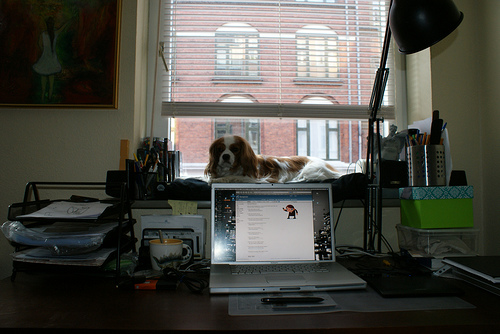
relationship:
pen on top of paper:
[258, 289, 330, 308] [282, 291, 339, 312]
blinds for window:
[155, 0, 398, 122] [154, 7, 415, 181]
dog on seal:
[199, 136, 339, 184] [174, 172, 363, 182]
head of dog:
[205, 133, 252, 175] [203, 132, 341, 181]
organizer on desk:
[6, 153, 144, 303] [0, 262, 491, 331]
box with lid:
[397, 183, 476, 226] [396, 182, 476, 201]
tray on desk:
[5, 176, 134, 228] [1, 239, 499, 332]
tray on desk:
[3, 213, 138, 253] [1, 239, 499, 332]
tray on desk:
[6, 244, 138, 292] [1, 239, 499, 332]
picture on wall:
[2, 1, 120, 112] [2, 0, 151, 279]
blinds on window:
[155, 0, 398, 122] [154, 7, 415, 181]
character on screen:
[265, 209, 322, 244] [215, 187, 328, 261]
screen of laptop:
[215, 187, 328, 261] [168, 149, 378, 324]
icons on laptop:
[219, 189, 236, 252] [207, 182, 366, 292]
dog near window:
[202, 134, 352, 184] [154, 7, 415, 181]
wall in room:
[3, 1, 151, 208] [440, 32, 495, 197]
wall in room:
[394, 0, 497, 256] [440, 32, 495, 197]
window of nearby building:
[208, 26, 280, 61] [176, 1, 384, 182]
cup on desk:
[130, 221, 203, 291] [121, 266, 499, 332]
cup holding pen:
[148, 237, 192, 269] [153, 227, 166, 242]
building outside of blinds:
[172, 9, 361, 141] [155, 0, 396, 120]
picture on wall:
[2, 1, 120, 112] [10, 113, 99, 166]